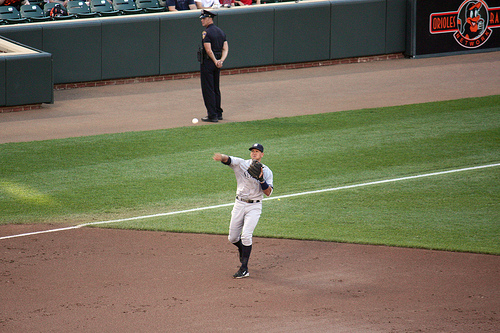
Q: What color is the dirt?
A: The dirt is brown.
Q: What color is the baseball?
A: The baseball is white.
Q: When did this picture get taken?
A: It was taken in the day time.